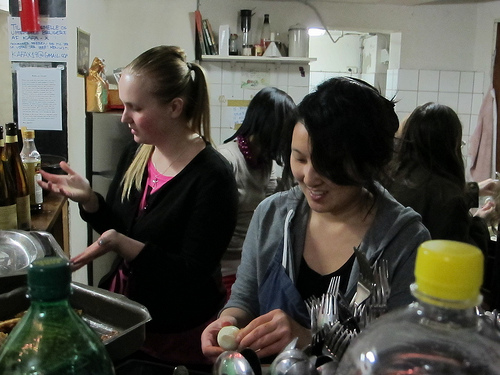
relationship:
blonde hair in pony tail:
[117, 38, 215, 203] [181, 59, 208, 108]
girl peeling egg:
[199, 75, 429, 365] [217, 325, 241, 349]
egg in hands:
[217, 325, 241, 349] [187, 298, 323, 368]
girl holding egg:
[199, 75, 429, 365] [217, 325, 241, 349]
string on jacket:
[277, 219, 292, 271] [254, 207, 286, 257]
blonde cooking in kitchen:
[35, 43, 240, 360] [7, 6, 498, 368]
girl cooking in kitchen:
[199, 75, 429, 365] [7, 6, 498, 368]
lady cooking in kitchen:
[214, 86, 296, 303] [7, 6, 498, 368]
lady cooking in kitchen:
[390, 101, 499, 298] [7, 6, 498, 368]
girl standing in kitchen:
[199, 75, 429, 365] [7, 6, 498, 368]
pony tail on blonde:
[118, 62, 213, 204] [35, 43, 240, 360]